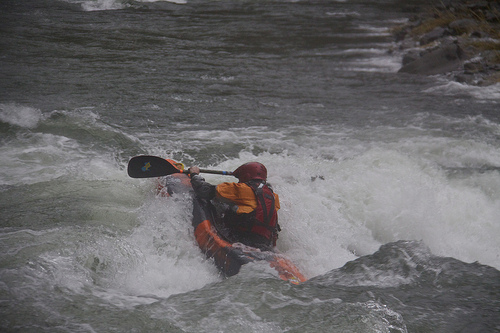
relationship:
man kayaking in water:
[188, 162, 281, 246] [17, 0, 499, 330]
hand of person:
[188, 166, 200, 175] [174, 156, 284, 256]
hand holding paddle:
[188, 166, 200, 175] [120, 149, 235, 186]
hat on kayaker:
[227, 156, 269, 196] [123, 130, 303, 284]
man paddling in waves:
[188, 162, 281, 246] [109, 116, 471, 328]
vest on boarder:
[223, 183, 288, 242] [118, 149, 299, 293]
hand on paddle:
[182, 165, 202, 175] [123, 154, 240, 178]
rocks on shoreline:
[387, 0, 494, 95] [315, 2, 497, 127]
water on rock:
[17, 0, 499, 330] [397, 32, 499, 87]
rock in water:
[24, 239, 499, 330] [17, 0, 499, 330]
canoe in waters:
[158, 176, 266, 257] [335, 141, 469, 239]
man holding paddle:
[170, 148, 289, 235] [126, 150, 241, 181]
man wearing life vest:
[188, 162, 281, 246] [239, 182, 276, 244]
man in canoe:
[188, 162, 281, 246] [157, 142, 308, 299]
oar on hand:
[120, 141, 260, 221] [185, 152, 197, 185]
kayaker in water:
[191, 158, 288, 273] [30, 62, 499, 328]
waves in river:
[326, 152, 413, 227] [22, 16, 482, 126]